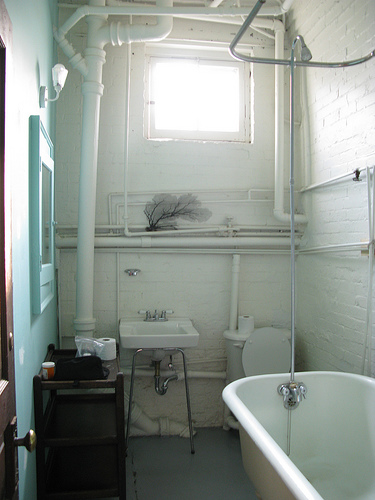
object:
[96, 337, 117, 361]
toilet paper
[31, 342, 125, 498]
wood stand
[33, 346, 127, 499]
shelf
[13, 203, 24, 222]
wall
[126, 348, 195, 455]
legs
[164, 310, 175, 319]
knobs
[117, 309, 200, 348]
sink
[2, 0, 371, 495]
bathroom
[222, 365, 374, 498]
bathtub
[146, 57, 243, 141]
window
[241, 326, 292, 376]
lid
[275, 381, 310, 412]
faucet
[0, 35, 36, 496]
door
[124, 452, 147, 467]
bad sentence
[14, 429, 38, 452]
knob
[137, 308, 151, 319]
left knob